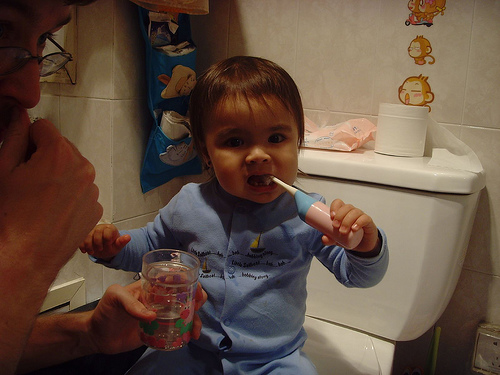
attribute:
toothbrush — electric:
[242, 160, 363, 252]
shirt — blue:
[129, 169, 328, 325]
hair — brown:
[184, 58, 320, 131]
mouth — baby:
[235, 168, 289, 188]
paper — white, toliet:
[363, 75, 463, 183]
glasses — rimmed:
[1, 29, 77, 83]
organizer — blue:
[141, 16, 201, 196]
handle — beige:
[426, 322, 446, 372]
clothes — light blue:
[88, 175, 389, 372]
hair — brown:
[185, 52, 307, 171]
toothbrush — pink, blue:
[263, 172, 363, 249]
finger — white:
[339, 204, 359, 237]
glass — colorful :
[137, 243, 198, 343]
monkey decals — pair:
[392, 12, 445, 116]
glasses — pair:
[10, 30, 82, 90]